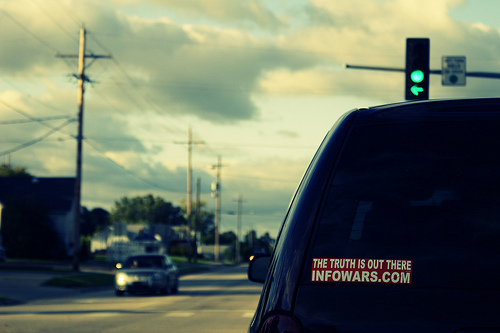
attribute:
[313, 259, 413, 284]
letters — white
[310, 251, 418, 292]
bumper sticker — red, white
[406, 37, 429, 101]
trafficlight — green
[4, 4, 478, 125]
clouds — fluffy, white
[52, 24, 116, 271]
utility pole — tall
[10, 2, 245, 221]
powerlines — electrical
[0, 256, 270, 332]
street — paved